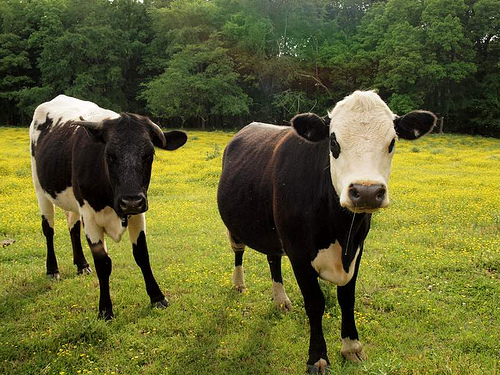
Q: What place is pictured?
A: It is a field.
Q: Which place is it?
A: It is a field.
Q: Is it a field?
A: Yes, it is a field.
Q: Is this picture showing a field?
A: Yes, it is showing a field.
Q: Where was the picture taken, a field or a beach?
A: It was taken at a field.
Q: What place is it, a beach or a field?
A: It is a field.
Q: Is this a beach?
A: No, it is a field.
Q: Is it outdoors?
A: Yes, it is outdoors.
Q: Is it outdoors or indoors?
A: It is outdoors.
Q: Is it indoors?
A: No, it is outdoors.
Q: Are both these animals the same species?
A: Yes, all the animals are cows.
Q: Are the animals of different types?
A: No, all the animals are cows.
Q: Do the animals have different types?
A: No, all the animals are cows.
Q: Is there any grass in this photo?
A: Yes, there is grass.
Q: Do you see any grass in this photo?
A: Yes, there is grass.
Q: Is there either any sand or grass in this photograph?
A: Yes, there is grass.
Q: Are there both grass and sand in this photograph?
A: No, there is grass but no sand.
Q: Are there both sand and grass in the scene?
A: No, there is grass but no sand.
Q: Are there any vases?
A: No, there are no vases.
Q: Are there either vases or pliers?
A: No, there are no vases or pliers.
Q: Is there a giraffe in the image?
A: No, there are no giraffes.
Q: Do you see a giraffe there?
A: No, there are no giraffes.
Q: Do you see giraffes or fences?
A: No, there are no giraffes or fences.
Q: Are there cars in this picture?
A: No, there are no cars.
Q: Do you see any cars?
A: No, there are no cars.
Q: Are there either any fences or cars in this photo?
A: No, there are no cars or fences.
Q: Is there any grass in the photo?
A: Yes, there is grass.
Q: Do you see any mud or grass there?
A: Yes, there is grass.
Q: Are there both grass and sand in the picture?
A: No, there is grass but no sand.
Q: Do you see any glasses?
A: No, there are no glasses.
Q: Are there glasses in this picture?
A: No, there are no glasses.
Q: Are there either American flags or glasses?
A: No, there are no glasses or American flags.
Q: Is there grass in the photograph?
A: Yes, there is grass.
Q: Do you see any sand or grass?
A: Yes, there is grass.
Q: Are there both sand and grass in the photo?
A: No, there is grass but no sand.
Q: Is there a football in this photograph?
A: No, there are no footballs.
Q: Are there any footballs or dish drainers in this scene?
A: No, there are no footballs or dish drainers.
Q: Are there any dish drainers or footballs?
A: No, there are no footballs or dish drainers.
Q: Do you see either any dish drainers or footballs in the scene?
A: No, there are no footballs or dish drainers.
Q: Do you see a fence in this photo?
A: No, there are no fences.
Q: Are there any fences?
A: No, there are no fences.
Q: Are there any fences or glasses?
A: No, there are no fences or glasses.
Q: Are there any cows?
A: Yes, there is a cow.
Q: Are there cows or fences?
A: Yes, there is a cow.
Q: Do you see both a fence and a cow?
A: No, there is a cow but no fences.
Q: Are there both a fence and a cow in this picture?
A: No, there is a cow but no fences.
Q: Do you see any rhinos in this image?
A: No, there are no rhinos.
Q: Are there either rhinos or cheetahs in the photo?
A: No, there are no rhinos or cheetahs.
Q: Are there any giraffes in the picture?
A: No, there are no giraffes.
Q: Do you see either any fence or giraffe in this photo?
A: No, there are no giraffes or fences.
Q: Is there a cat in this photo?
A: No, there are no cats.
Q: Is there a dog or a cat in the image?
A: No, there are no cats or dogs.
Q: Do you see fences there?
A: No, there are no fences.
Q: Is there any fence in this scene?
A: No, there are no fences.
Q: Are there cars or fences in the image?
A: No, there are no fences or cars.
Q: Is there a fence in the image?
A: No, there are no fences.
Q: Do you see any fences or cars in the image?
A: No, there are no fences or cars.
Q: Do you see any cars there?
A: No, there are no cars.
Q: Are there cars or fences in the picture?
A: No, there are no cars or fences.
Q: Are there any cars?
A: No, there are no cars.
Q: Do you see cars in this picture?
A: No, there are no cars.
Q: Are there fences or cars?
A: No, there are no cars or fences.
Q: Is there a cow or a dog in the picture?
A: Yes, there is a cow.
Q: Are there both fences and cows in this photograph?
A: No, there is a cow but no fences.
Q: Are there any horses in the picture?
A: No, there are no horses.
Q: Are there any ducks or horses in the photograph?
A: No, there are no horses or ducks.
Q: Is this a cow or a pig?
A: This is a cow.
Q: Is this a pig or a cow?
A: This is a cow.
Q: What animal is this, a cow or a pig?
A: This is a cow.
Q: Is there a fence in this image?
A: No, there are no fences.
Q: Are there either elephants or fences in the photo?
A: No, there are no fences or elephants.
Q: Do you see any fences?
A: No, there are no fences.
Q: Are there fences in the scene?
A: No, there are no fences.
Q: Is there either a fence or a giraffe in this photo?
A: No, there are no fences or giraffes.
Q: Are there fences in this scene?
A: No, there are no fences.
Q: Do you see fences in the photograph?
A: No, there are no fences.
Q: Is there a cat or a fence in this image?
A: No, there are no fences or cats.